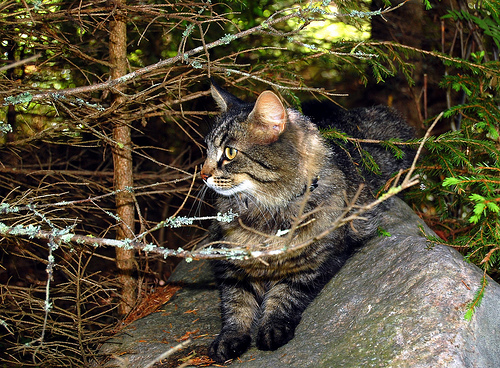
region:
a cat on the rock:
[123, 43, 446, 365]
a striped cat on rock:
[158, 113, 442, 345]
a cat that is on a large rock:
[200, 73, 474, 363]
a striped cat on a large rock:
[121, 34, 433, 354]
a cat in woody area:
[189, 52, 391, 347]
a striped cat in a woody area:
[114, 32, 374, 367]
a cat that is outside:
[135, 63, 433, 363]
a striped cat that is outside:
[150, 56, 365, 365]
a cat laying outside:
[182, 91, 472, 355]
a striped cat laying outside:
[153, 23, 474, 333]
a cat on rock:
[191, 78, 433, 363]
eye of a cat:
[219, 140, 243, 161]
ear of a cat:
[246, 89, 291, 144]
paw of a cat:
[255, 323, 297, 353]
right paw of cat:
[209, 324, 254, 366]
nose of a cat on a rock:
[191, 167, 211, 187]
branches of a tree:
[5, 280, 116, 365]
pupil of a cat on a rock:
[225, 146, 238, 156]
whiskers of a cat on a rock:
[173, 185, 302, 227]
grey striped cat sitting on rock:
[200, 82, 418, 360]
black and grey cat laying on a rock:
[201, 82, 423, 366]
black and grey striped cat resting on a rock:
[199, 82, 414, 364]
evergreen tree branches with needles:
[321, 37, 499, 320]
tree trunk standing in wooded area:
[106, 4, 136, 320]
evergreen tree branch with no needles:
[1, 111, 445, 341]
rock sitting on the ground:
[92, 192, 499, 367]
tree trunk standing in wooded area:
[367, 1, 425, 143]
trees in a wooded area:
[0, 2, 497, 319]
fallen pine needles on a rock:
[113, 282, 218, 366]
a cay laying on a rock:
[182, 78, 434, 363]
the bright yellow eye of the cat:
[222, 143, 237, 160]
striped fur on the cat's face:
[210, 115, 284, 185]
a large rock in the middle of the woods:
[96, 190, 498, 366]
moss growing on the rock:
[310, 305, 412, 366]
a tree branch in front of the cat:
[0, 154, 424, 283]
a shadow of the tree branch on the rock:
[119, 264, 256, 299]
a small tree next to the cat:
[32, 1, 217, 315]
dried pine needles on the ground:
[116, 282, 178, 328]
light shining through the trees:
[284, 1, 374, 43]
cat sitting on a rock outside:
[186, 75, 433, 355]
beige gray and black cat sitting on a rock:
[198, 80, 415, 350]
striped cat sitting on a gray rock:
[197, 80, 423, 357]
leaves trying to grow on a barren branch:
[163, 208, 238, 229]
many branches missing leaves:
[0, 120, 148, 351]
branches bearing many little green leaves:
[430, 45, 495, 265]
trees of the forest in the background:
[3, 0, 293, 146]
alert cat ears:
[207, 86, 292, 136]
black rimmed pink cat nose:
[195, 167, 213, 182]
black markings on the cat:
[244, 148, 286, 194]